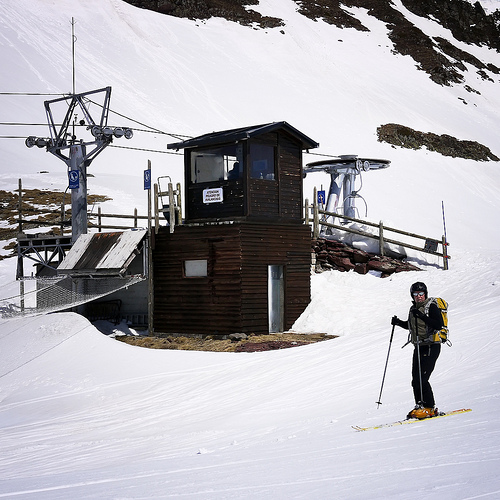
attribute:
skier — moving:
[392, 282, 448, 421]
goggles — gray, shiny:
[411, 290, 426, 298]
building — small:
[150, 122, 311, 332]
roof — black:
[168, 121, 319, 152]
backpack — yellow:
[429, 297, 450, 346]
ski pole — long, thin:
[373, 314, 400, 409]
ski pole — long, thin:
[412, 311, 429, 412]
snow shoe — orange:
[415, 407, 440, 422]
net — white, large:
[1, 278, 134, 324]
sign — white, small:
[203, 188, 225, 203]